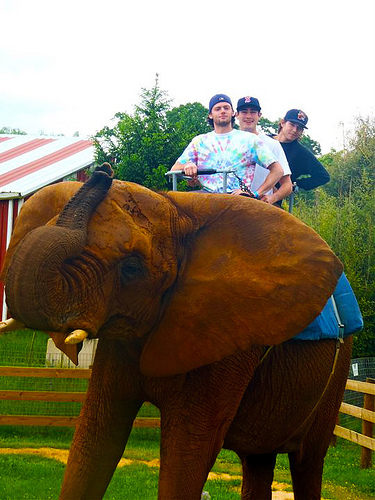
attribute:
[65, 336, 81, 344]
elephant tusk — ivory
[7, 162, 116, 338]
trunk — curled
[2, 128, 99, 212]
tent — white 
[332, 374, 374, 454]
fence — side 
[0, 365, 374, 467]
fence — brown , wooden 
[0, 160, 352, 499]
elephant — big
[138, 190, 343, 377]
ear — floppy 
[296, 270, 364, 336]
pad — blue 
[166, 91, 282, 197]
guy — three 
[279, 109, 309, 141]
head — guy's 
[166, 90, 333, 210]
guys — three , sitting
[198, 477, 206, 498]
rock — part 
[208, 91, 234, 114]
blue cap — blue 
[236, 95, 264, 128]
guy — smiling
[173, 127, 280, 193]
t-shirt — tie dyed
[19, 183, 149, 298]
trunk — brown 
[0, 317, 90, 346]
tusks — white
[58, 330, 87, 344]
horn — part 